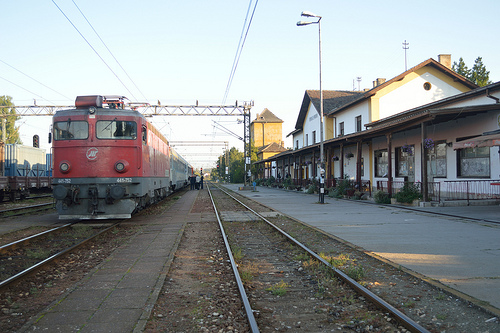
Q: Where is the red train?
A: Stopped on the tracks.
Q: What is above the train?
A: Power lines.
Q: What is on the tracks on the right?
A: Nothing.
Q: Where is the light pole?
A: Next to the station.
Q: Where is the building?
A: On the side of the platform.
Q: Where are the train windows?
A: On the front.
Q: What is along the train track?
A: Buildings.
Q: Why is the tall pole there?
A: To provide lighting.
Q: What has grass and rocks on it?
A: Train tracks.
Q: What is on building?
A: Chimney.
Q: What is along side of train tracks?
A: Paved area.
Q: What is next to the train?
A: Tracks.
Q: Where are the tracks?
A: On the ground.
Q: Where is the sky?
A: Above the ground.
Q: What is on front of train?
A: A light.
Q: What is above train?
A: Power lines.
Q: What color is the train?
A: Red.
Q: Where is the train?
A: On the tracks.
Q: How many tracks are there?
A: Three.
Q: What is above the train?
A: Power lines.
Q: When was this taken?
A: Daytime.